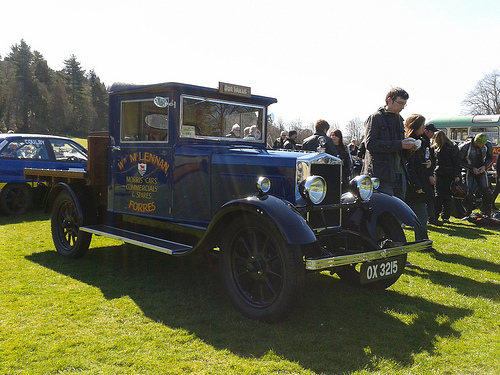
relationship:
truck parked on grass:
[116, 72, 384, 281] [33, 114, 490, 363]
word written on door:
[116, 157, 128, 169] [109, 91, 177, 219]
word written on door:
[129, 150, 171, 171] [109, 91, 177, 219]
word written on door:
[122, 175, 144, 182] [109, 91, 177, 219]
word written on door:
[124, 183, 160, 192] [109, 91, 177, 219]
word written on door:
[125, 199, 157, 214] [109, 91, 177, 219]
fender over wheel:
[186, 195, 318, 249] [211, 214, 300, 320]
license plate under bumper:
[359, 262, 413, 281] [303, 243, 448, 266]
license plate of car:
[359, 262, 413, 281] [21, 80, 433, 323]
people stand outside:
[227, 125, 257, 137] [1, 1, 498, 373]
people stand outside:
[272, 130, 297, 151] [1, 1, 498, 373]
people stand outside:
[302, 120, 363, 174] [1, 1, 498, 373]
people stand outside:
[364, 87, 461, 265] [1, 1, 498, 373]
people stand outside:
[461, 132, 493, 222] [1, 1, 498, 373]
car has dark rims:
[21, 80, 433, 323] [53, 190, 305, 322]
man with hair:
[360, 77, 423, 201] [386, 85, 409, 102]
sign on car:
[114, 152, 169, 215] [21, 80, 433, 323]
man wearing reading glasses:
[360, 77, 422, 179] [397, 101, 411, 108]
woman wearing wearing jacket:
[403, 110, 435, 247] [403, 133, 442, 243]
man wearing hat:
[466, 120, 498, 191] [469, 126, 497, 152]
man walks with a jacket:
[362, 78, 420, 243] [355, 105, 413, 185]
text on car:
[117, 150, 170, 212] [21, 80, 433, 323]